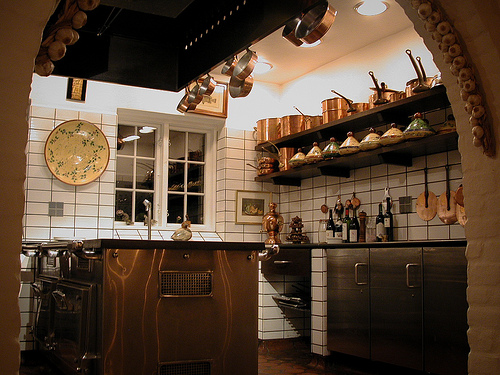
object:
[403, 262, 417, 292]
handle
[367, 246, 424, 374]
cupboard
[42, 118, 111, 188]
plate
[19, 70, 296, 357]
wall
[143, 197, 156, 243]
faucet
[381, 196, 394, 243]
bottle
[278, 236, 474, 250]
counter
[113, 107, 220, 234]
window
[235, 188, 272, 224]
picture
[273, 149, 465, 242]
back splash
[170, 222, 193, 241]
knick knack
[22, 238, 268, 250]
counter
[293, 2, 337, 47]
pan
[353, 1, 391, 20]
light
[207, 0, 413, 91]
ceiling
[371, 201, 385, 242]
bottle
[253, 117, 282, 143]
pot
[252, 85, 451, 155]
top shelf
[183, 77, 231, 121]
picture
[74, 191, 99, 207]
tile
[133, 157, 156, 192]
pane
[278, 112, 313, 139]
pot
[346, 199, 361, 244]
bottle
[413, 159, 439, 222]
fan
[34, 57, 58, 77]
garlic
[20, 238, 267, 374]
stove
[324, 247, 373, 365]
cupboard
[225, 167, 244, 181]
tile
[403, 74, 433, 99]
frying pan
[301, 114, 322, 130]
pot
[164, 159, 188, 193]
pane